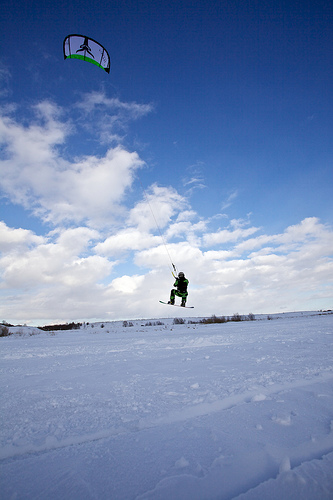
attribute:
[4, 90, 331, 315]
clouds — white, fluffy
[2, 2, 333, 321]
sky — clear, blue, bright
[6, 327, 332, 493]
snow — white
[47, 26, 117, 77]
kite — flying, blue, green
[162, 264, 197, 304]
man — snowboarding, skiing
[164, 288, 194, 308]
pants — green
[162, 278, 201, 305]
clothes — long sleeved